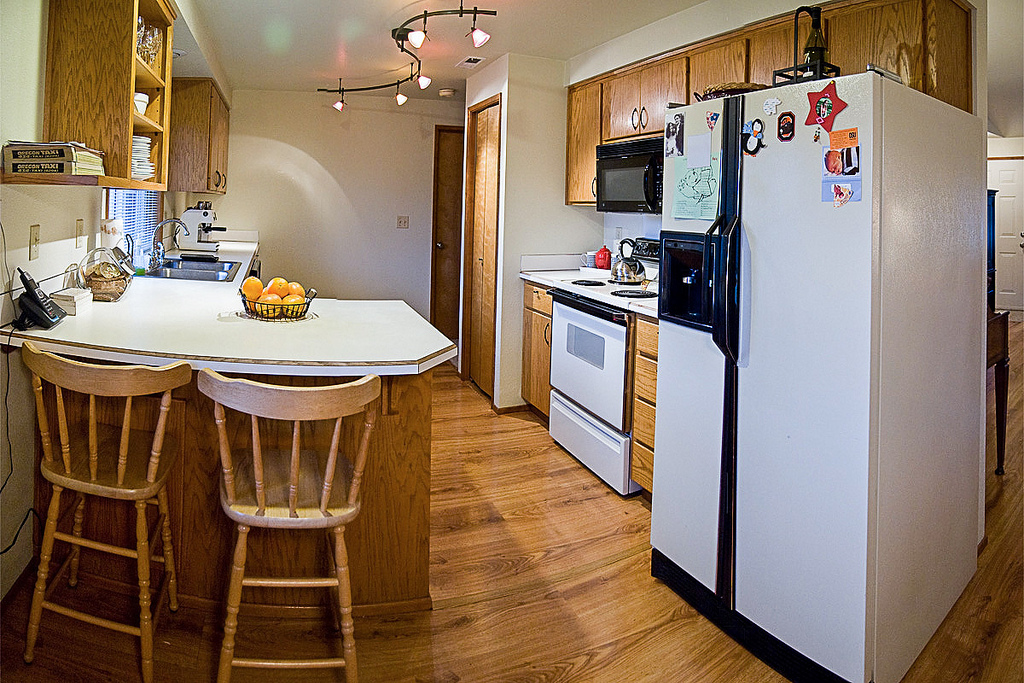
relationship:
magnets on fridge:
[740, 58, 862, 214] [645, 95, 941, 674]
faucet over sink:
[133, 201, 233, 278] [139, 245, 243, 282]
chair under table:
[245, 286, 420, 599] [1, 271, 460, 622]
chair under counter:
[24, 364, 260, 674] [3, 271, 461, 378]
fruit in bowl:
[231, 257, 320, 321] [232, 284, 328, 313]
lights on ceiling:
[302, 2, 498, 116] [197, 1, 718, 79]